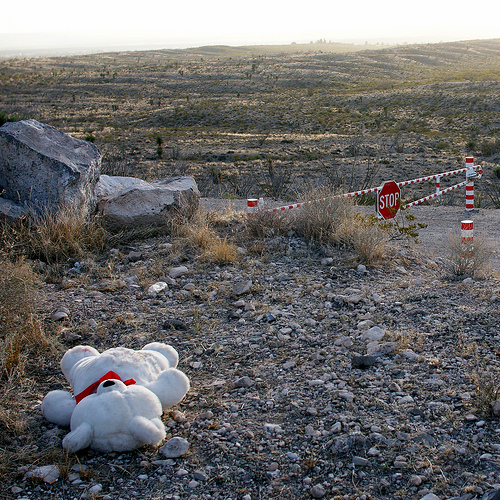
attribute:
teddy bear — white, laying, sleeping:
[36, 340, 193, 462]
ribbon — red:
[75, 374, 145, 399]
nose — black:
[98, 378, 118, 390]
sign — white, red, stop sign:
[376, 181, 405, 220]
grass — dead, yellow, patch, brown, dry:
[174, 210, 246, 268]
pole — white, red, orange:
[456, 158, 481, 209]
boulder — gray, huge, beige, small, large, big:
[3, 115, 211, 247]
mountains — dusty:
[4, 2, 496, 213]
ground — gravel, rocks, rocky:
[3, 226, 498, 499]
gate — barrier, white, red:
[235, 157, 470, 230]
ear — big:
[127, 417, 182, 447]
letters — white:
[378, 190, 402, 211]